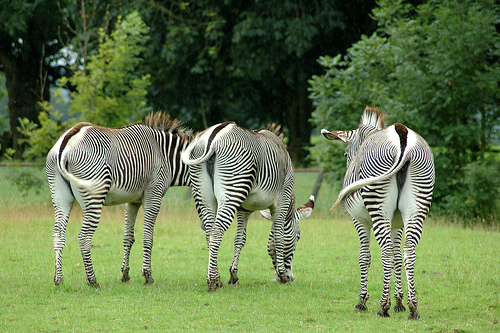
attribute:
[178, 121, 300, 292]
zebra — black, white, striped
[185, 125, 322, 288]
zebra — white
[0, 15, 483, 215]
plants — green , leafy , assorted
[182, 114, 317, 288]
zebra — white, striped, black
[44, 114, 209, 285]
zebra — white, striped, black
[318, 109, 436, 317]
zebra — striped, black, white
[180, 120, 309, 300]
zebra — black, white, striped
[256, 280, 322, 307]
grass — green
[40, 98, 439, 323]
zebras — sitting, eating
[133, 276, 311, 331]
grass — green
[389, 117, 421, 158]
stripe — long , black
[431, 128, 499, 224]
bush — green, leafy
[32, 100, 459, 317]
ebra — white, striped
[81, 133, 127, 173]
prints — black, white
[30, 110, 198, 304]
zebra — eating , black, white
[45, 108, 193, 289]
zebra — black